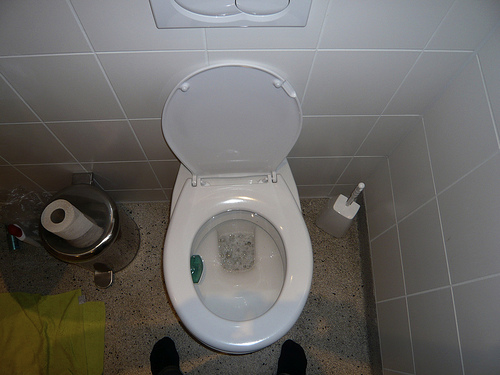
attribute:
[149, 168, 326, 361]
seat — down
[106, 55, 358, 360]
toilet — white 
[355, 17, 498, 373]
wall — White tile, white 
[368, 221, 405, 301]
tile — white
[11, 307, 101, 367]
towel — yellow 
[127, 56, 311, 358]
toilet — bathroom 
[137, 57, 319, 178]
lid — up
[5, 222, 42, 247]
bottle — White , plastic 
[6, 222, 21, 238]
top — red 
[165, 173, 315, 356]
seat — White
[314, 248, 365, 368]
floor —  light grey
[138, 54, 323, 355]
toilet — bathroom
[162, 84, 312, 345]
toilet bowl — green 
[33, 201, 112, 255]
roll — toilet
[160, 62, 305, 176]
toilet lid —  lid up 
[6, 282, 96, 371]
object — yellow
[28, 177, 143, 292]
can — silver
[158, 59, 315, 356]
toilet — Green , seat 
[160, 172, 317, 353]
seatguard — seat , lowered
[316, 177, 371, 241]
cleaner — White 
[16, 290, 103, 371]
towel — Yellow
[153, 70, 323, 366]
toilet — bathroom , white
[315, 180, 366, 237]
brush — white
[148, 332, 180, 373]
sock — black 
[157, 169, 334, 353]
toilet — white, bathroom 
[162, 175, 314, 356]
toilet seat — White 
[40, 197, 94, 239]
toilet paper — roll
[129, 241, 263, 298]
smelling nice — Something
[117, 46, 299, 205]
lid — white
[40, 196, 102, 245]
toilet paper —  roll 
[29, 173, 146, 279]
trashcan — Silver 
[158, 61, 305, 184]
lid — White 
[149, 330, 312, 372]
sock. — black 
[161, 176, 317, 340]
seat — down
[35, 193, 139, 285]
can — silver 